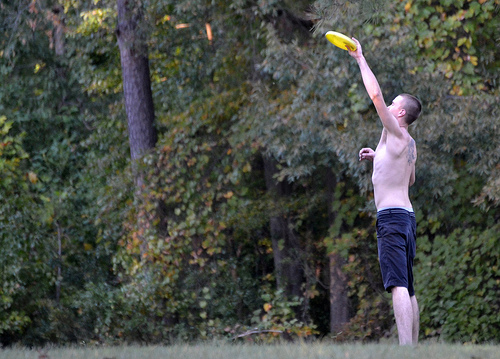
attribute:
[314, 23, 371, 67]
frisbee — yellow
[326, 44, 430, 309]
boy — shirtless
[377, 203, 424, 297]
shorts — black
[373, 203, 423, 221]
belt — gray